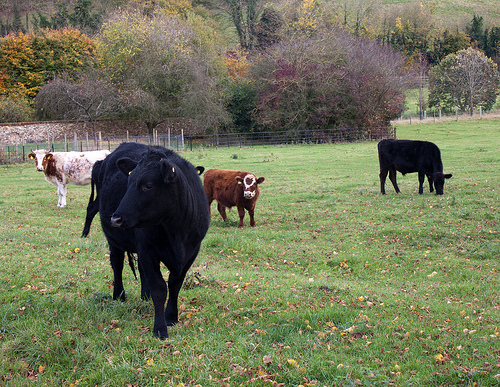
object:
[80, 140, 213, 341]
cow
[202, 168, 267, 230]
cow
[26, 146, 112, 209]
cow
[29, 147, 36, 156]
horns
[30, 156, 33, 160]
tag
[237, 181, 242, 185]
tag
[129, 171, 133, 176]
tag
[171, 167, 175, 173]
tag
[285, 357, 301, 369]
leaf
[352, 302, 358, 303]
leaves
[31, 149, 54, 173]
face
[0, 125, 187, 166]
fence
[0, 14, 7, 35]
trees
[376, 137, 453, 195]
cow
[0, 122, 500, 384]
grass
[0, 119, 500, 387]
field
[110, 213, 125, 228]
nose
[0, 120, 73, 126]
train track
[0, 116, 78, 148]
hill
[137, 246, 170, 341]
legs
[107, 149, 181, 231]
head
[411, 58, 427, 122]
trees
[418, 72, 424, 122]
trunk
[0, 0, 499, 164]
background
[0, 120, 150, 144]
wall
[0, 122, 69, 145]
stone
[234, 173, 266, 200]
head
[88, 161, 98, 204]
tail